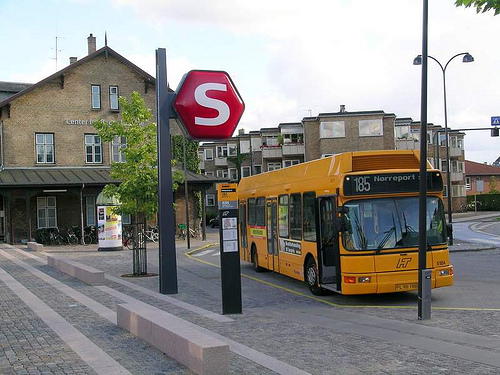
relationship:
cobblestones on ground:
[3, 330, 53, 371] [1, 241, 93, 374]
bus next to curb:
[237, 150, 453, 296] [184, 242, 499, 342]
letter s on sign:
[194, 82, 229, 124] [176, 68, 245, 142]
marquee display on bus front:
[338, 170, 444, 200] [337, 149, 454, 288]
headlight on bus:
[355, 273, 372, 284] [237, 150, 453, 296]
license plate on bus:
[387, 279, 429, 301] [228, 145, 465, 309]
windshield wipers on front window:
[367, 207, 425, 254] [342, 195, 451, 255]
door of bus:
[315, 193, 340, 300] [193, 151, 485, 343]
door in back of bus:
[238, 200, 248, 260] [237, 150, 453, 296]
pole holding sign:
[152, 150, 184, 217] [172, 62, 253, 142]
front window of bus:
[343, 198, 441, 248] [188, 137, 460, 329]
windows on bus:
[225, 193, 321, 239] [177, 114, 458, 335]